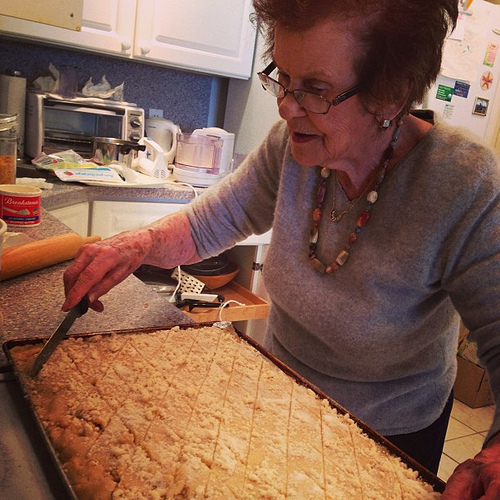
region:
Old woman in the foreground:
[46, 1, 496, 498]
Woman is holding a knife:
[10, 284, 95, 396]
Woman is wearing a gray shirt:
[167, 98, 499, 435]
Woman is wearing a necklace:
[276, 103, 416, 295]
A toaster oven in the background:
[22, 85, 154, 175]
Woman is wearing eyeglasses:
[245, 45, 365, 126]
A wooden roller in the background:
[0, 215, 113, 292]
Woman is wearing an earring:
[369, 113, 398, 140]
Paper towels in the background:
[1, 59, 32, 169]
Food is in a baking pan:
[3, 292, 459, 498]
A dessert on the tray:
[3, 320, 444, 498]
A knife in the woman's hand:
[29, 291, 94, 378]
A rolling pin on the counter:
[0, 230, 101, 278]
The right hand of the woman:
[65, 227, 145, 309]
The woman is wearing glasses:
[259, 63, 367, 115]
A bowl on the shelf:
[188, 263, 239, 287]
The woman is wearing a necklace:
[305, 118, 407, 272]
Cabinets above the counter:
[1, 0, 251, 80]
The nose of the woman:
[278, 93, 299, 117]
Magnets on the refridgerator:
[433, 73, 494, 119]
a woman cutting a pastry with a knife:
[25, 1, 496, 493]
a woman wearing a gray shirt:
[61, 5, 496, 498]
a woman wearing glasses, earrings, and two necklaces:
[57, 7, 497, 496]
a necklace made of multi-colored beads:
[305, 107, 412, 284]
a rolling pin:
[2, 222, 104, 289]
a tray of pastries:
[2, 315, 455, 497]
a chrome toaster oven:
[22, 86, 148, 174]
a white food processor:
[170, 123, 234, 188]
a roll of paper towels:
[0, 65, 35, 158]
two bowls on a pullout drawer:
[176, 252, 241, 294]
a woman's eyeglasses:
[251, 59, 361, 114]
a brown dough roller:
[0, 229, 102, 288]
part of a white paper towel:
[3, 71, 30, 151]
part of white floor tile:
[437, 402, 492, 480]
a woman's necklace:
[306, 110, 411, 274]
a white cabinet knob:
[117, 36, 132, 52]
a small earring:
[380, 119, 391, 129]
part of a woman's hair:
[247, 0, 464, 131]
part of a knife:
[27, 272, 90, 373]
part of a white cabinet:
[135, 0, 259, 77]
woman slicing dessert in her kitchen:
[31, 0, 498, 496]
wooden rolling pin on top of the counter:
[1, 227, 102, 286]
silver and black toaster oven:
[29, 101, 145, 157]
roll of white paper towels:
[4, 80, 32, 150]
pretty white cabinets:
[138, 4, 253, 76]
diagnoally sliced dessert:
[53, 328, 405, 498]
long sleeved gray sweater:
[267, 158, 499, 428]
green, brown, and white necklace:
[300, 163, 400, 283]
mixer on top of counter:
[176, 126, 243, 184]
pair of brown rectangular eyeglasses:
[251, 56, 374, 122]